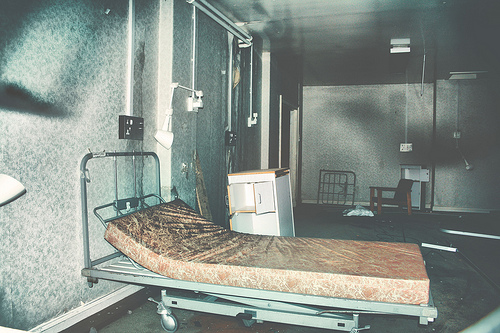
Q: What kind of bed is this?
A: An adjustable bed.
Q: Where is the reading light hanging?
A: By the bed.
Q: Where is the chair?
A: By the back wall.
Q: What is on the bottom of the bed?
A: Wheels.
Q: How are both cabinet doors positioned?
A: They are open.